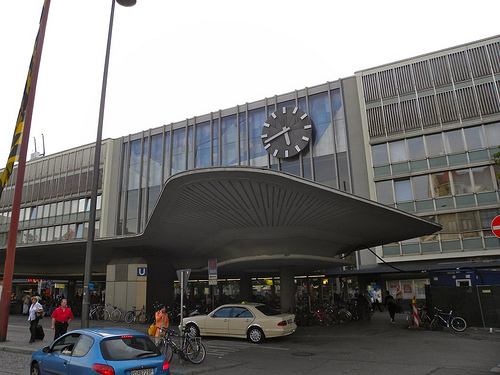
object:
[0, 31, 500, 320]
shopping center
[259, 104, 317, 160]
clock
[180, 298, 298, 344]
car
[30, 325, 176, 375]
car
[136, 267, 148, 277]
sign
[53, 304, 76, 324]
shirt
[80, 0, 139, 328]
lightpost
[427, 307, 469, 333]
bike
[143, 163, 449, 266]
overhang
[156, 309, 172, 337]
jacket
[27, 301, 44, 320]
blouse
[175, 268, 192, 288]
yield sign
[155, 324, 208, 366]
bikes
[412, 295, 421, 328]
pole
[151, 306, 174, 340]
dress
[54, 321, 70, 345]
pants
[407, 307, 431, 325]
bikes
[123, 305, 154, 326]
bikes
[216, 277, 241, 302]
doors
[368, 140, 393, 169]
windows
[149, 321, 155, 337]
handbag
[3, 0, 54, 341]
pole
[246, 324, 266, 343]
wheels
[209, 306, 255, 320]
windows